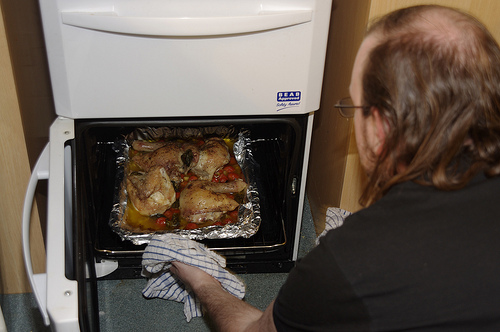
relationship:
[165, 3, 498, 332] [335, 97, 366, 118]
man wears glasses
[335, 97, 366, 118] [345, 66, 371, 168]
glasses are on face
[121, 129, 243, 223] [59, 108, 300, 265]
food in oven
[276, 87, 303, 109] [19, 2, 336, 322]
logo on oven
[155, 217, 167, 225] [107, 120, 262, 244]
carrot on pan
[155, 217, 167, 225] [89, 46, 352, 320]
carrot on pan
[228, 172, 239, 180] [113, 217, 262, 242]
carrot on pan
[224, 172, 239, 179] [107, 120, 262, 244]
carrot on pan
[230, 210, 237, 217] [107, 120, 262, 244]
carrot on pan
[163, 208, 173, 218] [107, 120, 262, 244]
carrot on pan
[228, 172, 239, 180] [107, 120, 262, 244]
carrot on pan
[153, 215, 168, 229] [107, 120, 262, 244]
carrot on pan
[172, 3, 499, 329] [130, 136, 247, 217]
man putting in chicken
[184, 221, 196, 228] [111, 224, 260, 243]
carrot in pan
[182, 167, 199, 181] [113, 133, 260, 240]
carrot on pan